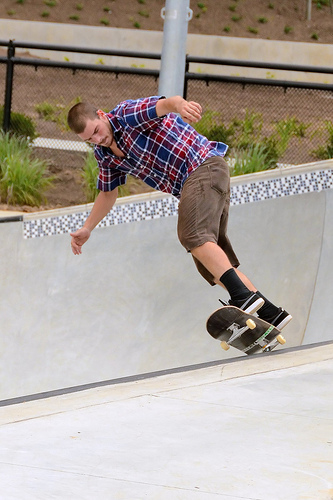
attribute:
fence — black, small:
[4, 37, 332, 132]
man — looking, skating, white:
[52, 84, 289, 314]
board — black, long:
[206, 303, 290, 365]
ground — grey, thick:
[4, 342, 327, 500]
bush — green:
[270, 109, 306, 148]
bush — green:
[29, 93, 65, 128]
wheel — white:
[221, 338, 231, 352]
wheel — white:
[244, 317, 258, 330]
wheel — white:
[270, 330, 285, 345]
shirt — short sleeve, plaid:
[96, 93, 230, 197]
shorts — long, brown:
[175, 149, 244, 285]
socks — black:
[223, 264, 250, 308]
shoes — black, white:
[223, 279, 294, 334]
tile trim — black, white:
[23, 166, 330, 244]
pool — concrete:
[5, 156, 330, 498]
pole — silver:
[158, 1, 191, 107]